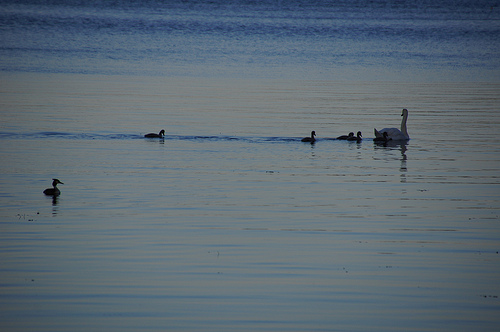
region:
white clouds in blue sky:
[31, 20, 88, 65]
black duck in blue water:
[40, 167, 66, 217]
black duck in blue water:
[135, 112, 165, 148]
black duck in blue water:
[295, 122, 320, 152]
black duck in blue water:
[343, 111, 368, 154]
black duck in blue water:
[376, 90, 418, 155]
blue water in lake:
[175, 226, 233, 267]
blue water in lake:
[286, 241, 363, 283]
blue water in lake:
[415, 243, 453, 278]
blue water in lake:
[201, 206, 242, 242]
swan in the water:
[371, 105, 420, 149]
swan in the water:
[352, 124, 368, 144]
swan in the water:
[336, 125, 356, 143]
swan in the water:
[300, 127, 318, 146]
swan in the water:
[144, 124, 168, 140]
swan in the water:
[37, 174, 66, 200]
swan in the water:
[368, 128, 388, 145]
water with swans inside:
[1, 1, 498, 330]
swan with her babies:
[24, 97, 417, 225]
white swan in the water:
[367, 107, 414, 144]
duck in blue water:
[35, 171, 69, 203]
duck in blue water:
[365, 99, 410, 159]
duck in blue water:
[292, 120, 328, 162]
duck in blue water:
[328, 118, 370, 157]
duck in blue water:
[129, 121, 176, 155]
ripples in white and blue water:
[186, 206, 234, 258]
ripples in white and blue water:
[228, 20, 274, 79]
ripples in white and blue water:
[274, 197, 331, 277]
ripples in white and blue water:
[144, 214, 221, 275]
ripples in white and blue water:
[374, 256, 443, 316]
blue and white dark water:
[46, 30, 134, 75]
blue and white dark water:
[173, 241, 218, 264]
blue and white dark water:
[279, 223, 299, 259]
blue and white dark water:
[303, 212, 353, 267]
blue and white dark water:
[176, 177, 217, 221]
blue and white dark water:
[96, 13, 178, 70]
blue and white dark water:
[408, 215, 436, 259]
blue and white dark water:
[216, 41, 282, 95]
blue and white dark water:
[323, 16, 367, 68]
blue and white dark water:
[109, 6, 160, 61]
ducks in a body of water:
[30, 97, 453, 219]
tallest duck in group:
[375, 100, 415, 140]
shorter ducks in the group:
[35, 110, 390, 210]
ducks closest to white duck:
[301, 120, 388, 150]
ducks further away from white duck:
[35, 110, 170, 215]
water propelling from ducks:
[36, 121, 141, 141]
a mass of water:
[2, 5, 492, 313]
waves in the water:
[272, 220, 472, 295]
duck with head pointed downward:
[131, 128, 178, 148]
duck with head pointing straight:
[41, 166, 79, 202]